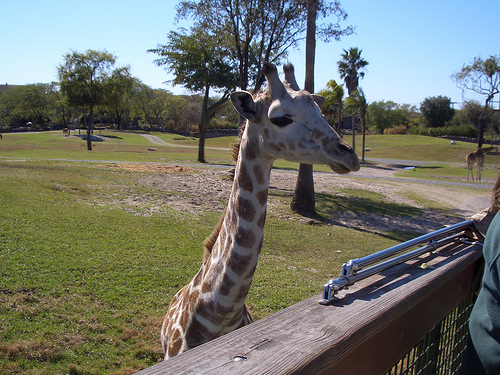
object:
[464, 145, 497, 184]
giraffe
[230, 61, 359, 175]
head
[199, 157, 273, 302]
neck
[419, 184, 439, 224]
ground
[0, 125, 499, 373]
grass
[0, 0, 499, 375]
park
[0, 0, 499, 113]
sky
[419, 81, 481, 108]
clouds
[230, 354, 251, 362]
nail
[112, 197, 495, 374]
wood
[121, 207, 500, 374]
fence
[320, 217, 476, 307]
metal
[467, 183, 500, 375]
jumper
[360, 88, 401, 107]
clouds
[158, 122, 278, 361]
fur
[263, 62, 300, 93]
head horns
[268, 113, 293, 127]
eye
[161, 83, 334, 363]
skin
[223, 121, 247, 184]
hair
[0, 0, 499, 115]
blue sky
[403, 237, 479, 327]
wooden fence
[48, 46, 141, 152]
tree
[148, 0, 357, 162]
tree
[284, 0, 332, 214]
tree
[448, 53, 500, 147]
tree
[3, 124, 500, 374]
pen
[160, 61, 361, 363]
animal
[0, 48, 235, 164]
distance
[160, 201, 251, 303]
back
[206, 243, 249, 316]
patterns